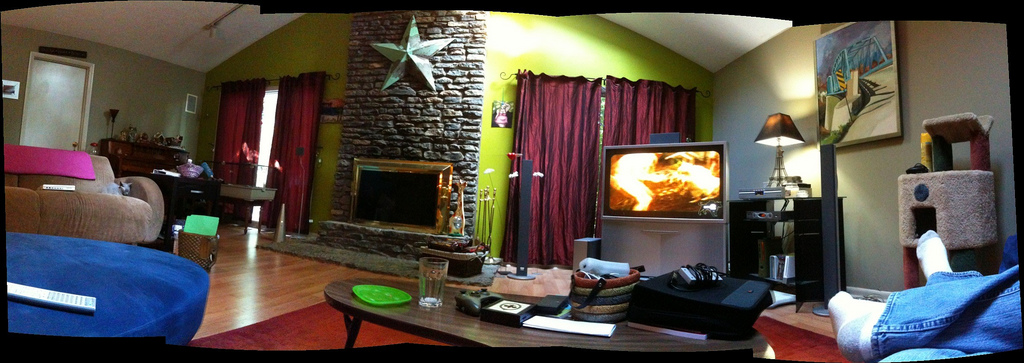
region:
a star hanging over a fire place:
[377, 22, 458, 95]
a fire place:
[335, 146, 463, 235]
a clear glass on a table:
[417, 250, 453, 318]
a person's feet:
[831, 222, 959, 360]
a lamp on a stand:
[750, 101, 805, 191]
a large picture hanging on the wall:
[812, 26, 912, 145]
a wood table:
[310, 256, 763, 361]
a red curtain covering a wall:
[253, 63, 320, 248]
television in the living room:
[593, 136, 730, 274]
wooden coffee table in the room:
[323, 274, 776, 357]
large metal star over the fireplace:
[373, 19, 453, 90]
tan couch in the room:
[1, 140, 167, 245]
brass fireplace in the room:
[333, 151, 466, 232]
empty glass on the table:
[415, 255, 447, 310]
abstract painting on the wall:
[810, 18, 908, 145]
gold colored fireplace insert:
[342, 153, 451, 233]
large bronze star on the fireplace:
[367, 13, 454, 93]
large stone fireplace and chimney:
[320, 1, 494, 265]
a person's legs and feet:
[828, 226, 1022, 359]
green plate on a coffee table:
[349, 273, 411, 309]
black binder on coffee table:
[624, 261, 776, 338]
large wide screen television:
[595, 134, 732, 284]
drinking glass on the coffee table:
[414, 254, 450, 309]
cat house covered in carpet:
[895, 111, 1003, 288]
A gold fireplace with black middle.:
[345, 153, 454, 239]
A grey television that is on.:
[595, 144, 731, 277]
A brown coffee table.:
[319, 274, 771, 360]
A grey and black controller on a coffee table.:
[670, 261, 727, 290]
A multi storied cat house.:
[901, 114, 999, 289]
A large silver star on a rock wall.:
[364, 17, 454, 101]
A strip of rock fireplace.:
[321, 11, 483, 277]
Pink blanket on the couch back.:
[1, 140, 96, 183]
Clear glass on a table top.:
[414, 255, 450, 312]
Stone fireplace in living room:
[311, 1, 476, 268]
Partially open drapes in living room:
[213, 70, 324, 245]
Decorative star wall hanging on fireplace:
[359, 10, 455, 99]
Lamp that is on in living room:
[754, 109, 806, 192]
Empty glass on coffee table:
[409, 250, 451, 309]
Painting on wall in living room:
[806, 17, 905, 147]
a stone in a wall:
[440, 87, 467, 104]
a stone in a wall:
[415, 109, 451, 120]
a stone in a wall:
[440, 112, 459, 119]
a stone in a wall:
[446, 119, 472, 136]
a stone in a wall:
[440, 136, 459, 143]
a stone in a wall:
[412, 147, 438, 151]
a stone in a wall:
[457, 152, 474, 165]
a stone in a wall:
[463, 197, 473, 207]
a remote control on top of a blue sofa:
[4, 273, 99, 318]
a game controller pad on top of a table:
[452, 283, 507, 322]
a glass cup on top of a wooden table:
[412, 251, 451, 312]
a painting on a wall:
[809, 14, 908, 154]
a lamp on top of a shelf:
[752, 110, 807, 193]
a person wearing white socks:
[825, 226, 963, 360]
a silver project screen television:
[597, 138, 734, 285]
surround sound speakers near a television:
[504, 126, 852, 323]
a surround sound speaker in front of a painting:
[810, 138, 852, 319]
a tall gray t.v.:
[596, 130, 726, 277]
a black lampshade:
[751, 105, 806, 151]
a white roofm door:
[21, 42, 89, 157]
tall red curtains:
[507, 59, 607, 275]